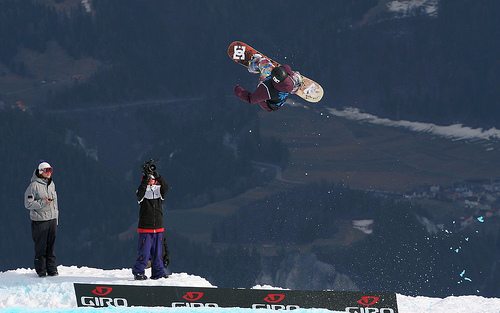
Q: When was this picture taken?
A: Daytime.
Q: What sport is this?
A: Snowboarding.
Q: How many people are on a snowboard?
A: 1.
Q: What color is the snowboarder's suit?
A: Purple.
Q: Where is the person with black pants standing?
A: On the left.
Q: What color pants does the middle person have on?
A: Blue.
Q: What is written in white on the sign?
A: Giro.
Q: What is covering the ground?
A: Snow.